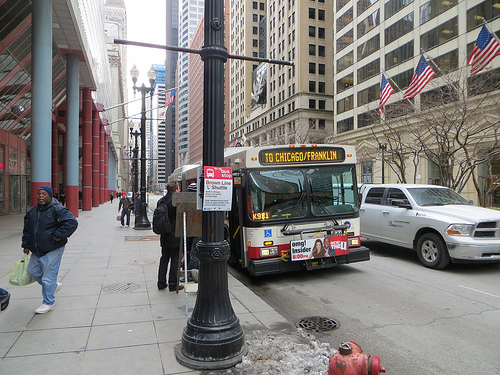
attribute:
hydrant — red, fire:
[322, 337, 390, 373]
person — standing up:
[113, 187, 133, 228]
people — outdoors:
[13, 173, 185, 320]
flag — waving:
[402, 53, 438, 102]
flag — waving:
[459, 20, 499, 81]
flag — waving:
[372, 71, 399, 107]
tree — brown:
[381, 98, 497, 198]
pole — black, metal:
[170, 13, 250, 373]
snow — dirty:
[253, 320, 333, 372]